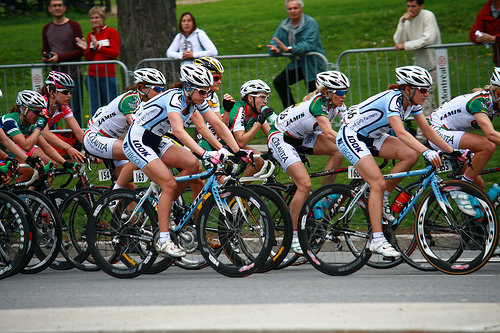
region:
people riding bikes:
[11, 76, 492, 234]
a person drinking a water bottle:
[237, 86, 283, 130]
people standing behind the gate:
[43, 5, 498, 53]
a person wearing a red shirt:
[82, 7, 120, 88]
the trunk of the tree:
[119, 9, 177, 64]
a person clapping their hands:
[271, 5, 319, 70]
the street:
[21, 245, 484, 329]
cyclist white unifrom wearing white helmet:
[115, 54, 235, 256]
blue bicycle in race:
[83, 141, 281, 280]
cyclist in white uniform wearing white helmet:
[261, 64, 362, 258]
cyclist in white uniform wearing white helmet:
[332, 60, 459, 259]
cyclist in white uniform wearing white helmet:
[424, 63, 499, 205]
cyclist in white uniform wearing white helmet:
[79, 63, 175, 213]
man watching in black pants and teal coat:
[264, 0, 329, 112]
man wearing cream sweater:
[393, 0, 450, 111]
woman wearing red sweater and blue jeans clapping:
[71, 1, 126, 110]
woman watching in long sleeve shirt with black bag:
[160, 10, 223, 90]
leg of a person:
[136, 161, 200, 248]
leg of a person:
[280, 171, 335, 246]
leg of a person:
[353, 165, 397, 238]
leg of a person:
[311, 139, 353, 196]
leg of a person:
[383, 157, 428, 199]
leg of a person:
[445, 145, 488, 210]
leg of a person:
[105, 161, 130, 205]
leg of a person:
[75, 65, 115, 122]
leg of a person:
[305, 70, 337, 99]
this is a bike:
[94, 140, 276, 282]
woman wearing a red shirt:
[65, 10, 122, 70]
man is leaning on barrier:
[263, 0, 378, 110]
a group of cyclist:
[0, 23, 487, 278]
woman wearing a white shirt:
[159, 28, 236, 70]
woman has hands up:
[71, 25, 107, 60]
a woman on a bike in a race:
[125, 70, 217, 252]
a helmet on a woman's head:
[182, 62, 211, 87]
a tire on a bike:
[194, 187, 271, 278]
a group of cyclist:
[4, 50, 499, 300]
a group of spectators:
[36, 2, 496, 105]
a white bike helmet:
[165, 61, 225, 103]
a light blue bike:
[309, 141, 498, 263]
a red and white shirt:
[71, 30, 125, 76]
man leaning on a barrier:
[251, 4, 342, 104]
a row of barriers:
[15, 32, 498, 156]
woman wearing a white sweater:
[154, 25, 222, 72]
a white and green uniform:
[253, 85, 350, 176]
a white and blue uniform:
[309, 77, 426, 184]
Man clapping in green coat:
[260, 0, 336, 110]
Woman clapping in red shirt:
[70, 5, 125, 114]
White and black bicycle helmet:
[174, 63, 216, 94]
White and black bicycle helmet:
[237, 76, 271, 99]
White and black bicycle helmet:
[314, 68, 357, 95]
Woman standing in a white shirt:
[164, 6, 224, 70]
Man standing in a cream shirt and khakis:
[391, 0, 445, 142]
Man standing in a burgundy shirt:
[39, 2, 87, 139]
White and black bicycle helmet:
[16, 89, 51, 116]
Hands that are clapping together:
[261, 37, 291, 59]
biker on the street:
[75, 55, 275, 280]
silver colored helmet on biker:
[170, 60, 215, 87]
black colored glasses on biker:
[180, 80, 202, 91]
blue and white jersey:
[121, 87, 192, 168]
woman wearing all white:
[161, 7, 217, 72]